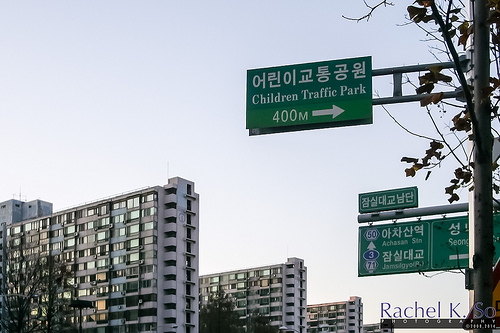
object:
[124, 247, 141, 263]
building window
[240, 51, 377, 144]
sign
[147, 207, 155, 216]
window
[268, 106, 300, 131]
white number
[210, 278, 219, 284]
window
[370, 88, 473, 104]
pole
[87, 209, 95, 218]
window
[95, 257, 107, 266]
window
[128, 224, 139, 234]
window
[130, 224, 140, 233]
window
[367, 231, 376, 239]
numbers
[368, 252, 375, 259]
numbers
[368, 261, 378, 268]
numbers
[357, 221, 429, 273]
sign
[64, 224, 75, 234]
window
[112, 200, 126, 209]
window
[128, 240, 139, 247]
window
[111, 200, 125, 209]
window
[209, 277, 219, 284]
window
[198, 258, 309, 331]
building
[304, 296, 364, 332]
building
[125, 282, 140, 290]
window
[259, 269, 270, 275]
window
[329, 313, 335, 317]
window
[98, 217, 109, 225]
window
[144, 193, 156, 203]
window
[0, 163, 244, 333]
building